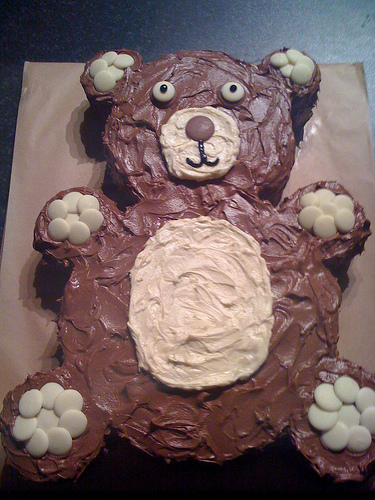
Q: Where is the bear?
A: On a tray.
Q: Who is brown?
A: The bear.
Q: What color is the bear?
A: Brown.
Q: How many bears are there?
A: One.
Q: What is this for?
A: A celebration.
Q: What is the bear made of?
A: Cake.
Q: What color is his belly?
A: Beige.